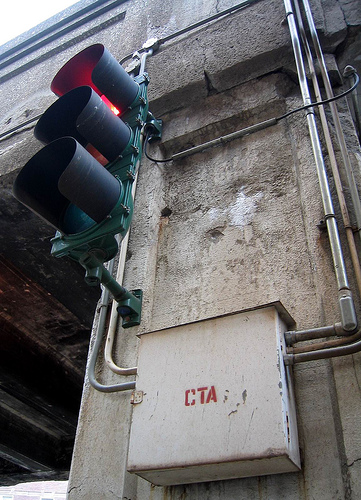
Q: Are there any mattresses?
A: No, there are no mattresses.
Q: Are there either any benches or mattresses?
A: No, there are no mattresses or benches.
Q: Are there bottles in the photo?
A: No, there are no bottles.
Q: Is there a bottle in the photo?
A: No, there are no bottles.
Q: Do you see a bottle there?
A: No, there are no bottles.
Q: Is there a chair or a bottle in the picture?
A: No, there are no bottles or chairs.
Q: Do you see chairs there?
A: No, there are no chairs.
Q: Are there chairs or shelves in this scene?
A: No, there are no chairs or shelves.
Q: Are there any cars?
A: No, there are no cars.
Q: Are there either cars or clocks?
A: No, there are no cars or clocks.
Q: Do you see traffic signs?
A: Yes, there is a traffic sign.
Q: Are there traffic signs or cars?
A: Yes, there is a traffic sign.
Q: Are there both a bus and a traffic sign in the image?
A: No, there is a traffic sign but no buses.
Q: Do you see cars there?
A: No, there are no cars.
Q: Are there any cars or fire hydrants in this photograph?
A: No, there are no cars or fire hydrants.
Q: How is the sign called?
A: The sign is a traffic sign.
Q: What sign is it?
A: The sign is a traffic sign.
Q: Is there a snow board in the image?
A: No, there are no snowboards.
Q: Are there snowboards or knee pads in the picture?
A: No, there are no snowboards or knee pads.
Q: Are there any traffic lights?
A: Yes, there is a traffic light.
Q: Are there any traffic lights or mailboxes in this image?
A: Yes, there is a traffic light.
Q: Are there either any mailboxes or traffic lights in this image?
A: Yes, there is a traffic light.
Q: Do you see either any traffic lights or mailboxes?
A: Yes, there is a traffic light.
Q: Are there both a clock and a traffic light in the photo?
A: No, there is a traffic light but no clocks.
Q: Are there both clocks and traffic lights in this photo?
A: No, there is a traffic light but no clocks.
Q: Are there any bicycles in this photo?
A: No, there are no bicycles.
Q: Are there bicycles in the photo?
A: No, there are no bicycles.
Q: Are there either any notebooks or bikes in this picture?
A: No, there are no bikes or notebooks.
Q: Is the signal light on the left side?
A: Yes, the signal light is on the left of the image.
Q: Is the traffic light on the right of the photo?
A: No, the traffic light is on the left of the image.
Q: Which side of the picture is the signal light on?
A: The signal light is on the left of the image.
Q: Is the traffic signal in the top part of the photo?
A: Yes, the traffic signal is in the top of the image.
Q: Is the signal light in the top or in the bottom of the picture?
A: The signal light is in the top of the image.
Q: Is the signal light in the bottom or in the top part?
A: The signal light is in the top of the image.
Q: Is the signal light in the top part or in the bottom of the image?
A: The signal light is in the top of the image.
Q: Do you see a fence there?
A: No, there are no fences.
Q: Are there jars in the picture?
A: No, there are no jars.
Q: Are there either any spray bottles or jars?
A: No, there are no jars or spray bottles.